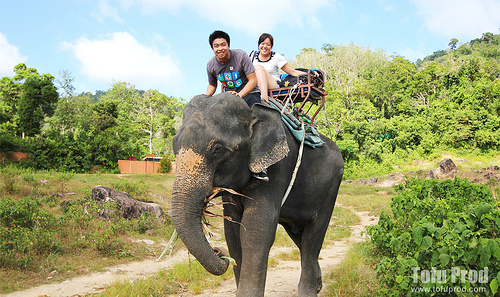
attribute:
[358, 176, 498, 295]
bush — green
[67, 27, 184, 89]
cloud — white 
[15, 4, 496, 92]
sky — blue , light 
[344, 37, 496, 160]
trees — green , tall 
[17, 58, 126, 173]
tree — green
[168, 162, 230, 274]
trunk — brown, elephant's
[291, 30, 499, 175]
trees — tall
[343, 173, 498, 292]
bushes — green, healthy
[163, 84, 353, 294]
elephant — gray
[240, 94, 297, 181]
elephant's ear — brown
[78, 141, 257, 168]
wall — short, red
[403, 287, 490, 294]
lettering — white 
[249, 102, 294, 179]
ear — small 